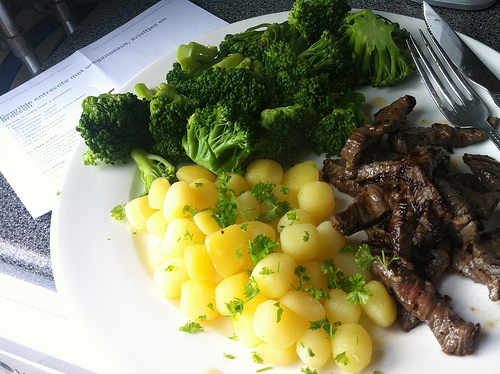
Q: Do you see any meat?
A: Yes, there is meat.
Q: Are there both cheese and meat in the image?
A: No, there is meat but no cheese.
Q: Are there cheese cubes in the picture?
A: No, there are no cheese cubes.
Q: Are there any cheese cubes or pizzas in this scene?
A: No, there are no cheese cubes or pizzas.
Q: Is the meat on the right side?
A: Yes, the meat is on the right of the image.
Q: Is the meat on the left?
A: No, the meat is on the right of the image.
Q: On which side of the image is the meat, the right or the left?
A: The meat is on the right of the image.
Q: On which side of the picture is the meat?
A: The meat is on the right of the image.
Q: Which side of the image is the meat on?
A: The meat is on the right of the image.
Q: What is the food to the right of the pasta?
A: The food is meat.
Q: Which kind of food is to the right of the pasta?
A: The food is meat.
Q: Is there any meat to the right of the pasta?
A: Yes, there is meat to the right of the pasta.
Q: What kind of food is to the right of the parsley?
A: The food is meat.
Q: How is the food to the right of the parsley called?
A: The food is meat.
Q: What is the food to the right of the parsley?
A: The food is meat.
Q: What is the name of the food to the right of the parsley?
A: The food is meat.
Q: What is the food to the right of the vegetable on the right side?
A: The food is meat.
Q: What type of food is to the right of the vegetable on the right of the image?
A: The food is meat.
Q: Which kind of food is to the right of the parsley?
A: The food is meat.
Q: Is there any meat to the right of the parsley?
A: Yes, there is meat to the right of the parsley.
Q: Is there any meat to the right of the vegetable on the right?
A: Yes, there is meat to the right of the parsley.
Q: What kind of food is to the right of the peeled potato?
A: The food is meat.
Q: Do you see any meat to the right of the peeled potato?
A: Yes, there is meat to the right of the potato.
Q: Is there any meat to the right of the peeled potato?
A: Yes, there is meat to the right of the potato.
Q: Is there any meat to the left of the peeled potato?
A: No, the meat is to the right of the potato.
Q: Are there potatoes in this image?
A: Yes, there is a potato.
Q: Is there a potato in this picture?
A: Yes, there is a potato.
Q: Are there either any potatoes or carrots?
A: Yes, there is a potato.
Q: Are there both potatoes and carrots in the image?
A: No, there is a potato but no carrots.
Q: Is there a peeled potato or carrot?
A: Yes, there is a peeled potato.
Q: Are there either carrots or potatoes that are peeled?
A: Yes, the potato is peeled.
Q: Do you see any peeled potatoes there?
A: Yes, there is a peeled potato.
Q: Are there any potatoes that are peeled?
A: Yes, there is a potato that is peeled.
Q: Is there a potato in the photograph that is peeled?
A: Yes, there is a potato that is peeled.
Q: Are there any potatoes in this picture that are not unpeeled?
A: Yes, there is an peeled potato.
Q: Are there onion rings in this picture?
A: No, there are no onion rings.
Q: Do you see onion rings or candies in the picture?
A: No, there are no onion rings or candies.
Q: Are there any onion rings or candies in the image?
A: No, there are no onion rings or candies.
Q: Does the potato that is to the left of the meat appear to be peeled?
A: Yes, the potato is peeled.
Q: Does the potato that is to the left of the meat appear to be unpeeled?
A: No, the potato is peeled.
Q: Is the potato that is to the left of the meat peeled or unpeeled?
A: The potato is peeled.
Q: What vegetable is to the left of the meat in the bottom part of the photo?
A: The vegetable is a potato.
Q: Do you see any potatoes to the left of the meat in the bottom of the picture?
A: Yes, there is a potato to the left of the meat.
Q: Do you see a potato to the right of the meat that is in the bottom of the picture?
A: No, the potato is to the left of the meat.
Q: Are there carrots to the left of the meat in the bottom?
A: No, there is a potato to the left of the meat.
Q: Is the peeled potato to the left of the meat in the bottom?
A: Yes, the potato is to the left of the meat.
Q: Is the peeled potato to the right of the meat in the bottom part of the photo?
A: No, the potato is to the left of the meat.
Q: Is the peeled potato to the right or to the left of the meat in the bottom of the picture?
A: The potato is to the left of the meat.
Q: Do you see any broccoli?
A: Yes, there is broccoli.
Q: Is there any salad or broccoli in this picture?
A: Yes, there is broccoli.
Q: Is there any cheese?
A: No, there is no cheese.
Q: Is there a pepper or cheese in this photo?
A: No, there are no cheese or peppers.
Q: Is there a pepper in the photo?
A: No, there are no peppers.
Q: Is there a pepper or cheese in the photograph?
A: No, there are no peppers or cheese.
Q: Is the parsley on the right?
A: Yes, the parsley is on the right of the image.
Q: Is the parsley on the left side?
A: No, the parsley is on the right of the image.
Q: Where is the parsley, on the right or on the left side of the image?
A: The parsley is on the right of the image.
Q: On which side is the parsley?
A: The parsley is on the right of the image.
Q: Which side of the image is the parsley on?
A: The parsley is on the right of the image.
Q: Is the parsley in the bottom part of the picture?
A: Yes, the parsley is in the bottom of the image.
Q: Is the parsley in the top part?
A: No, the parsley is in the bottom of the image.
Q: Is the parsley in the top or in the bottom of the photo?
A: The parsley is in the bottom of the image.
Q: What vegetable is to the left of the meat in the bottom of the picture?
A: The vegetable is parsley.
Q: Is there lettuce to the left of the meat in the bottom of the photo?
A: No, there is parsley to the left of the meat.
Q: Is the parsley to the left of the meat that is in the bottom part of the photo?
A: Yes, the parsley is to the left of the meat.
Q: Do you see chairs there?
A: No, there are no chairs.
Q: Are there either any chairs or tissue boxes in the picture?
A: No, there are no chairs or tissue boxes.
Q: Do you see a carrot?
A: No, there are no carrots.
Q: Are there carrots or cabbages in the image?
A: No, there are no carrots or cabbages.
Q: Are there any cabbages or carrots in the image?
A: No, there are no carrots or cabbages.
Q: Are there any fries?
A: No, there are no fries.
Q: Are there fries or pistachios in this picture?
A: No, there are no fries or pistachios.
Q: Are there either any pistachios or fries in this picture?
A: No, there are no fries or pistachios.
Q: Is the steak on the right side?
A: Yes, the steak is on the right of the image.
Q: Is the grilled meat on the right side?
A: Yes, the steak is on the right of the image.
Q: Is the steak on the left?
A: No, the steak is on the right of the image.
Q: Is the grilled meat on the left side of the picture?
A: No, the steak is on the right of the image.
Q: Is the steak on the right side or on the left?
A: The steak is on the right of the image.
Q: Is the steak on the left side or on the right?
A: The steak is on the right of the image.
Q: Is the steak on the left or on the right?
A: The steak is on the right of the image.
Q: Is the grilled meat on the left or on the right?
A: The steak is on the right of the image.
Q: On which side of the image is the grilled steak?
A: The steak is on the right of the image.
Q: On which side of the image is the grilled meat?
A: The steak is on the right of the image.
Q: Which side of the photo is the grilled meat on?
A: The steak is on the right of the image.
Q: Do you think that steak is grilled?
A: Yes, the steak is grilled.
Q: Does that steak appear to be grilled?
A: Yes, the steak is grilled.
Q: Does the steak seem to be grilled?
A: Yes, the steak is grilled.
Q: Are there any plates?
A: Yes, there is a plate.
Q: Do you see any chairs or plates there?
A: Yes, there is a plate.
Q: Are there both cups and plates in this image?
A: No, there is a plate but no cups.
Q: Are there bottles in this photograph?
A: No, there are no bottles.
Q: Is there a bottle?
A: No, there are no bottles.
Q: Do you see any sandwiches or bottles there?
A: No, there are no bottles or sandwiches.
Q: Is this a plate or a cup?
A: This is a plate.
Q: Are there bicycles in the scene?
A: No, there are no bicycles.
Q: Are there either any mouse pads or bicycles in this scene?
A: No, there are no bicycles or mouse pads.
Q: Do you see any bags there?
A: No, there are no bags.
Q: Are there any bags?
A: No, there are no bags.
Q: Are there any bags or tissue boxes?
A: No, there are no bags or tissue boxes.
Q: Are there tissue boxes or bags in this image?
A: No, there are no bags or tissue boxes.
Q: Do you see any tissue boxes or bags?
A: No, there are no bags or tissue boxes.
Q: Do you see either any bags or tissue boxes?
A: No, there are no bags or tissue boxes.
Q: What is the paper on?
A: The paper is on the counter.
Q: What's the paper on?
A: The paper is on the counter.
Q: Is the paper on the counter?
A: Yes, the paper is on the counter.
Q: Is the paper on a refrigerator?
A: No, the paper is on the counter.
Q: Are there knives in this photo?
A: Yes, there is a knife.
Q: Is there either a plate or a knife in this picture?
A: Yes, there is a knife.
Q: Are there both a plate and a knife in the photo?
A: Yes, there are both a knife and a plate.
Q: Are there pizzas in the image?
A: No, there are no pizzas.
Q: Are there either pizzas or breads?
A: No, there are no pizzas or breads.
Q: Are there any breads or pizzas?
A: No, there are no pizzas or breads.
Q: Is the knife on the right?
A: Yes, the knife is on the right of the image.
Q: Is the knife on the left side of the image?
A: No, the knife is on the right of the image.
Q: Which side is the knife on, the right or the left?
A: The knife is on the right of the image.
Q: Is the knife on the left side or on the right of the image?
A: The knife is on the right of the image.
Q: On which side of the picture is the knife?
A: The knife is on the right of the image.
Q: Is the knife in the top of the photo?
A: Yes, the knife is in the top of the image.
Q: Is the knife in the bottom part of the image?
A: No, the knife is in the top of the image.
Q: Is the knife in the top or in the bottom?
A: The knife is in the top of the image.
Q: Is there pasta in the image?
A: Yes, there is pasta.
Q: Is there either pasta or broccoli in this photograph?
A: Yes, there is pasta.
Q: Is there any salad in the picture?
A: No, there is no salad.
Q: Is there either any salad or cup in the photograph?
A: No, there are no salad or cups.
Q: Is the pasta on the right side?
A: Yes, the pasta is on the right of the image.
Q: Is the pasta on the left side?
A: No, the pasta is on the right of the image.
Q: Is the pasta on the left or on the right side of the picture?
A: The pasta is on the right of the image.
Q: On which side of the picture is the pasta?
A: The pasta is on the right of the image.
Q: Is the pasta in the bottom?
A: Yes, the pasta is in the bottom of the image.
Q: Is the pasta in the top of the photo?
A: No, the pasta is in the bottom of the image.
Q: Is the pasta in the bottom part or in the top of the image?
A: The pasta is in the bottom of the image.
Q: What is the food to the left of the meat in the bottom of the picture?
A: The food is pasta.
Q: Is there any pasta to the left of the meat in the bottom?
A: Yes, there is pasta to the left of the meat.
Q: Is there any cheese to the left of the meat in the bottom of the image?
A: No, there is pasta to the left of the meat.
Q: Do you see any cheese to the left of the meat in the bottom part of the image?
A: No, there is pasta to the left of the meat.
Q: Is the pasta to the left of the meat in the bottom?
A: Yes, the pasta is to the left of the meat.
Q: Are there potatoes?
A: Yes, there is a potato.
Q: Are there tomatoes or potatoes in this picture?
A: Yes, there is a potato.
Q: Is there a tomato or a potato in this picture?
A: Yes, there is a potato.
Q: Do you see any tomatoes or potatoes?
A: Yes, there is a potato.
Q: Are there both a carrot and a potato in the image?
A: No, there is a potato but no carrots.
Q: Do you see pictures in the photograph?
A: No, there are no pictures.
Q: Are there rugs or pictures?
A: No, there are no pictures or rugs.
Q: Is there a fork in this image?
A: Yes, there is a fork.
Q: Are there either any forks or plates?
A: Yes, there is a fork.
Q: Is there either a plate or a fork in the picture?
A: Yes, there is a fork.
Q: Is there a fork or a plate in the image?
A: Yes, there is a fork.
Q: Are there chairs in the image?
A: No, there are no chairs.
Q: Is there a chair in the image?
A: No, there are no chairs.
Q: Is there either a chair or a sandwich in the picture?
A: No, there are no chairs or sandwiches.